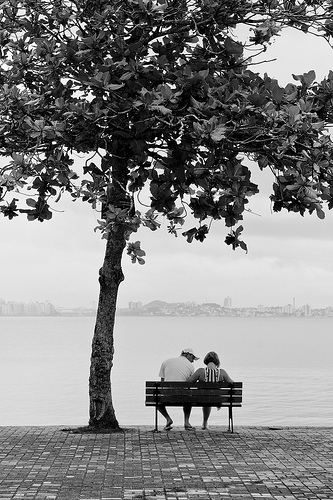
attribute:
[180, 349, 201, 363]
cap — white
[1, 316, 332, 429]
water — large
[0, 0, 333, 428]
tree — large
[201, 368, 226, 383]
shirt — white, striped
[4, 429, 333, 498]
walkway — cobblestone, pavement, brick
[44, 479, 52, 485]
tile — white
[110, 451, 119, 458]
tile — gray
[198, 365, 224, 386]
lines — black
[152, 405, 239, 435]
legs — dark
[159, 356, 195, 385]
shirt — wrinkled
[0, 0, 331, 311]
sky — blue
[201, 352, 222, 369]
hair — short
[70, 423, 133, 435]
hole — large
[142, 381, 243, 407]
bench — black, wooden